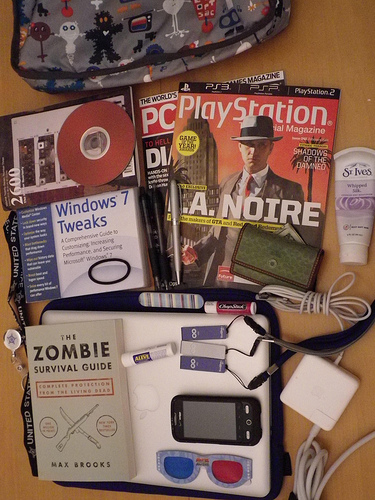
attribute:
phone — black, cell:
[167, 389, 261, 446]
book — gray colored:
[20, 316, 142, 489]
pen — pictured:
[168, 175, 183, 285]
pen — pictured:
[150, 184, 165, 288]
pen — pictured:
[137, 183, 160, 291]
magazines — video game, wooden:
[128, 71, 370, 312]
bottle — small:
[330, 148, 372, 265]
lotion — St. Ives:
[334, 146, 374, 267]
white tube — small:
[120, 343, 178, 368]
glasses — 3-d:
[155, 449, 253, 488]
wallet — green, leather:
[227, 220, 327, 294]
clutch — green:
[229, 220, 325, 293]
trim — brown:
[230, 224, 338, 289]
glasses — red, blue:
[139, 433, 287, 498]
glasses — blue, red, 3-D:
[152, 456, 253, 481]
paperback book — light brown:
[23, 318, 138, 480]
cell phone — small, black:
[165, 392, 263, 447]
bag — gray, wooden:
[4, 3, 324, 105]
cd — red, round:
[55, 100, 133, 186]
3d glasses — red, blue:
[153, 445, 256, 491]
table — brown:
[2, 15, 364, 497]